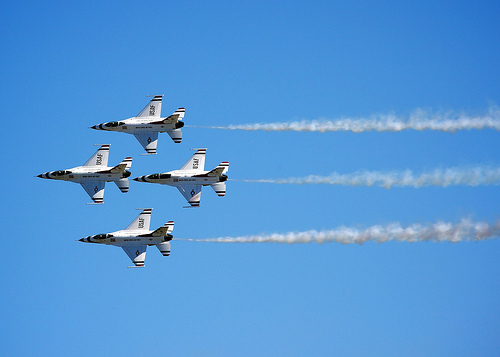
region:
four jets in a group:
[26, 90, 234, 272]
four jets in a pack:
[32, 74, 235, 279]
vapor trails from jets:
[210, 103, 498, 253]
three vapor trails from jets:
[193, 103, 499, 250]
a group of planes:
[35, 91, 237, 271]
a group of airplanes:
[23, 93, 238, 273]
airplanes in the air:
[32, 84, 237, 281]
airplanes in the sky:
[17, 85, 256, 281]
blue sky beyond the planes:
[31, 45, 360, 330]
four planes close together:
[30, 78, 235, 271]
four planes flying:
[13, 65, 253, 280]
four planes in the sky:
[25, 86, 236, 291]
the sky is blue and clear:
[25, 7, 240, 72]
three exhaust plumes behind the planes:
[240, 115, 497, 255]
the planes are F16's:
[15, 81, 250, 288]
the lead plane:
[15, 132, 140, 207]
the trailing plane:
[131, 136, 246, 211]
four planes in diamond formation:
[20, 74, 245, 284]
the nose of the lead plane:
[29, 163, 54, 183]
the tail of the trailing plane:
[206, 160, 236, 200]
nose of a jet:
[88, 123, 96, 131]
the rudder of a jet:
[154, 223, 169, 236]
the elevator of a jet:
[127, 250, 148, 265]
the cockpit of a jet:
[53, 168, 71, 176]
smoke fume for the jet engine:
[223, 230, 453, 240]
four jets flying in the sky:
[17, 97, 243, 280]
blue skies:
[45, 267, 366, 331]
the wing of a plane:
[123, 247, 153, 267]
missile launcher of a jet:
[83, 201, 110, 205]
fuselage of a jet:
[68, 168, 98, 178]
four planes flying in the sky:
[42, 67, 229, 299]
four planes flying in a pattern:
[40, 66, 247, 303]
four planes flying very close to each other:
[15, 74, 248, 309]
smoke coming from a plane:
[154, 214, 489, 270]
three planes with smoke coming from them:
[145, 80, 439, 287]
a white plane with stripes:
[35, 144, 140, 203]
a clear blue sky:
[146, 21, 433, 89]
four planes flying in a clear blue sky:
[20, 39, 247, 306]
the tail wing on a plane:
[137, 212, 177, 270]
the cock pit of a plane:
[88, 225, 118, 246]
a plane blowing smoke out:
[80, 207, 482, 274]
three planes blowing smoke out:
[110, 84, 402, 271]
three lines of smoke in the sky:
[261, 88, 483, 299]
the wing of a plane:
[107, 244, 153, 272]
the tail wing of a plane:
[145, 208, 180, 255]